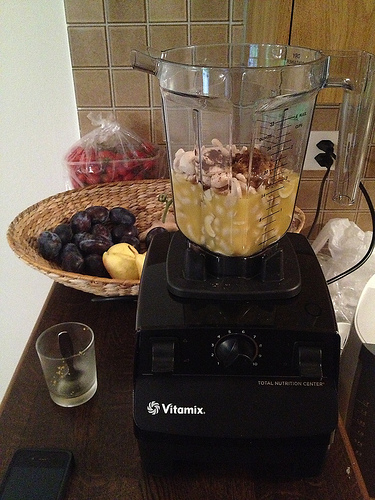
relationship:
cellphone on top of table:
[6, 449, 70, 497] [99, 464, 146, 492]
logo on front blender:
[144, 399, 209, 423] [126, 39, 374, 489]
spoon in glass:
[56, 330, 84, 381] [34, 320, 98, 407]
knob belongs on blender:
[219, 337, 251, 377] [141, 67, 336, 396]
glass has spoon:
[30, 317, 103, 410] [54, 326, 90, 395]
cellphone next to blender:
[6, 449, 70, 497] [126, 39, 374, 489]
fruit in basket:
[36, 190, 142, 294] [6, 177, 179, 291]